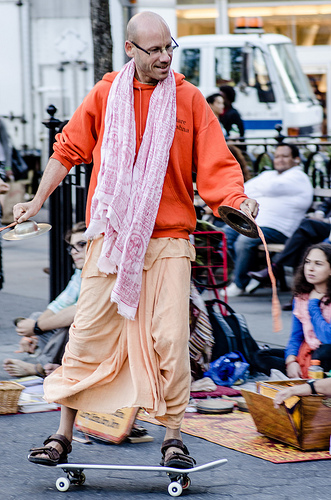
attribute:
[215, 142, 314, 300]
man — sitting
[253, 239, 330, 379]
woman — sitting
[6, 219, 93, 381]
man — sitting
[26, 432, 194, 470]
sandals — brown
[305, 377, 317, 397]
wristwatch — black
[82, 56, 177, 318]
scarf — pink, long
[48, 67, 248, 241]
jacket — orange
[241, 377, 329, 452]
box — wood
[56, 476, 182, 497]
wheels — white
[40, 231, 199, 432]
skirt — peach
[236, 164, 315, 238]
top — white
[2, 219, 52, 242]
bell — bronze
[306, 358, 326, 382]
bottle — plastic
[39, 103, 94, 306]
railing — black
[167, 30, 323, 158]
vehicle — white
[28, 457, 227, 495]
skaterboard — white